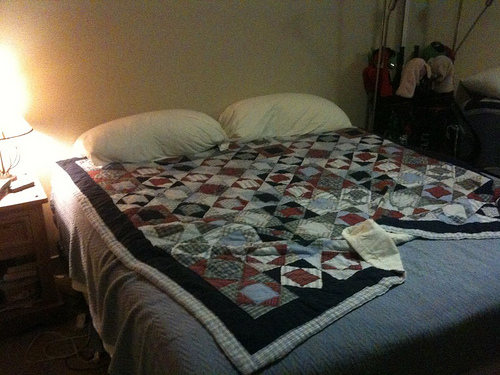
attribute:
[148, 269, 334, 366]
quilt — fancy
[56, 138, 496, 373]
bedspread — blue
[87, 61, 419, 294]
bedroom — indoor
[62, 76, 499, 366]
quilt — fancy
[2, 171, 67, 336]
night stand — wooden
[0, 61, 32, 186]
lamp — on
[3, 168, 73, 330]
nightstand — brown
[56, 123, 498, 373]
quilt — fancy, designed, multi-color and patchwork, navy blue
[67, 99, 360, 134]
pillows — white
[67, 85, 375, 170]
bed pillows — white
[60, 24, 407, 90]
walls — plain crema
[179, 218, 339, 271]
quilt — fancy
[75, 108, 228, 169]
pillow — white